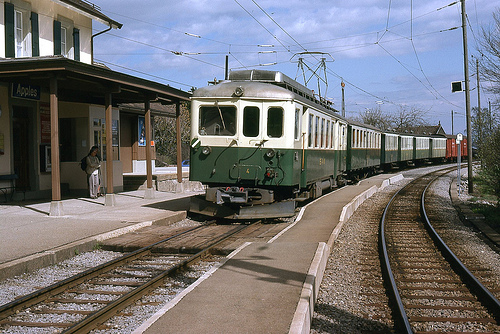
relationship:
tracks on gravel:
[0, 218, 253, 333] [23, 249, 210, 324]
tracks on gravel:
[98, 250, 176, 275] [82, 255, 195, 294]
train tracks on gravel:
[376, 163, 500, 333] [342, 235, 476, 271]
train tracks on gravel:
[376, 163, 500, 333] [393, 224, 434, 269]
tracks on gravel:
[0, 218, 253, 333] [0, 220, 246, 331]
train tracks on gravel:
[313, 163, 483, 320] [308, 167, 482, 302]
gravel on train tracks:
[310, 156, 495, 332] [377, 158, 498, 330]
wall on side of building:
[11, 85, 161, 198] [3, 4, 190, 203]